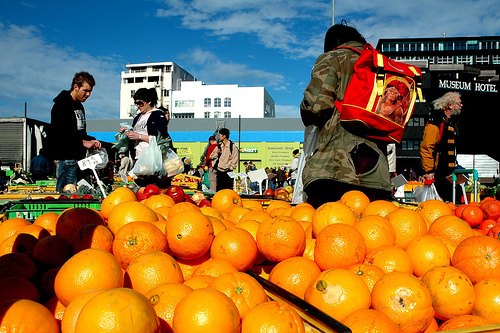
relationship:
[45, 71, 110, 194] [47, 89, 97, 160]
man in sweater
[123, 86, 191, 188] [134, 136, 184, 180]
woman carrying bags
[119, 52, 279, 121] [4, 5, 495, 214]
building in background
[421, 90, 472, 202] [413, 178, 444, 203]
man holding bags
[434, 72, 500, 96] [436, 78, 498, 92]
sign reading museum hotel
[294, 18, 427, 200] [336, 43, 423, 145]
man with book bag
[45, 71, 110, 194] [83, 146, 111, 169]
man holding bag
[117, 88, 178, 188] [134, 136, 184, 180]
woman holding bags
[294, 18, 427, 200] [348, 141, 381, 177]
man has hole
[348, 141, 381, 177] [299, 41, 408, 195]
hole in jacket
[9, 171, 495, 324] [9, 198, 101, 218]
oranges in cartons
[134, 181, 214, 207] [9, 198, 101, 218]
apples in cartons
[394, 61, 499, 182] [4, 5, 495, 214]
hotel in background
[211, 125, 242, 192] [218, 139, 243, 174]
man wearing jacket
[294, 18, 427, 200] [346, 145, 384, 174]
man with patch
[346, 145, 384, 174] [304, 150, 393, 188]
patch at bottom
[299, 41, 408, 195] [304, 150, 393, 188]
jacket has bottom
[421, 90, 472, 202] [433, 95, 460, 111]
man with hair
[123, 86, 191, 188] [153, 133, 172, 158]
woman with purse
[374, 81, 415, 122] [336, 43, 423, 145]
decal on book bag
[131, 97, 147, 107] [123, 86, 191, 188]
sunglasses worn by woman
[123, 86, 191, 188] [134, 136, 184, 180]
woman holding bags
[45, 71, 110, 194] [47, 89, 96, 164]
man wearing sweater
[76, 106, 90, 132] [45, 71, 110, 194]
design worn by man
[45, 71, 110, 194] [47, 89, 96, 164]
man in sweater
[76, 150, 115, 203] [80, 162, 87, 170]
sign with number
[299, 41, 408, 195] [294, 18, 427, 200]
jacket worn by man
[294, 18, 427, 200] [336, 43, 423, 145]
man carrying book bag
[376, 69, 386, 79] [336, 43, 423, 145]
snap on book bag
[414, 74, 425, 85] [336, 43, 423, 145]
snap on book bag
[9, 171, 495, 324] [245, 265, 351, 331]
oranges in baskets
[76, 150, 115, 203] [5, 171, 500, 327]
sign for produce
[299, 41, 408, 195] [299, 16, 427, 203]
jacket on woman